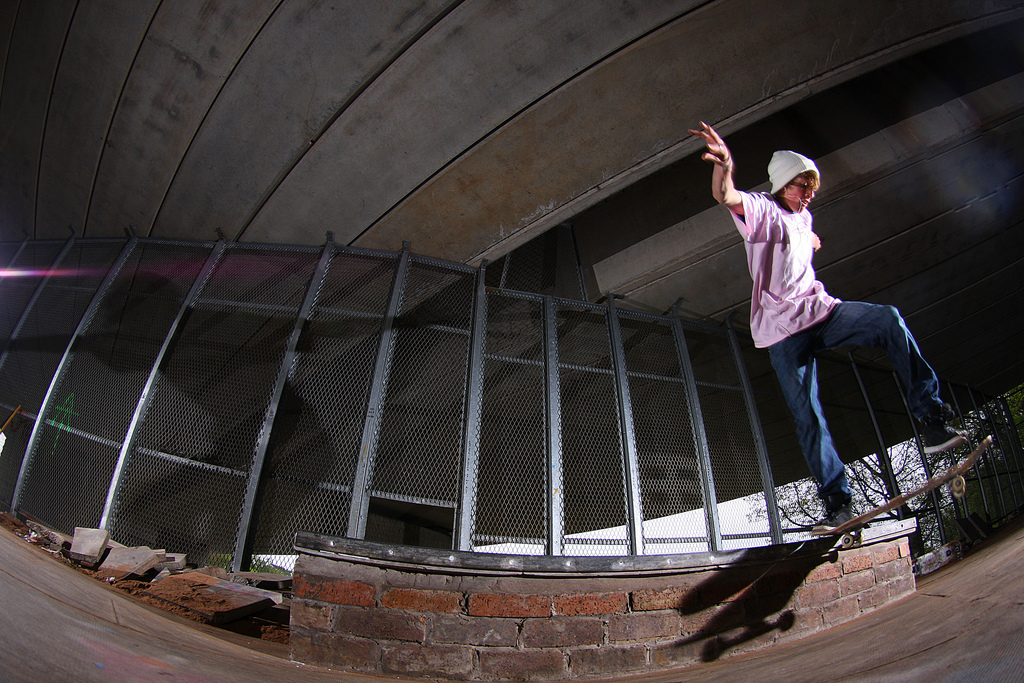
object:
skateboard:
[802, 430, 984, 552]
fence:
[6, 233, 1014, 571]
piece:
[61, 512, 113, 567]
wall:
[280, 541, 926, 678]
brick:
[286, 552, 379, 607]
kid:
[676, 119, 1024, 565]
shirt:
[714, 239, 874, 354]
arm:
[691, 164, 738, 214]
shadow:
[676, 513, 827, 665]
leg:
[747, 336, 846, 503]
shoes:
[790, 472, 864, 539]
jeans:
[738, 284, 952, 514]